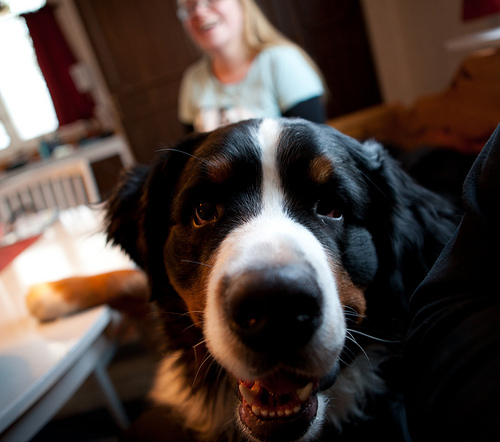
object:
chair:
[397, 47, 499, 146]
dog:
[100, 117, 458, 442]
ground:
[345, 82, 392, 113]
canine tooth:
[239, 382, 315, 418]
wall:
[377, 0, 452, 73]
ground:
[375, 86, 403, 119]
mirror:
[102, 105, 467, 433]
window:
[2, 0, 72, 142]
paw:
[21, 282, 68, 324]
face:
[167, 120, 372, 440]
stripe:
[252, 114, 292, 223]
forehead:
[175, 123, 364, 203]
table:
[0, 205, 143, 442]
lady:
[175, 0, 330, 132]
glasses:
[174, 4, 196, 20]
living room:
[4, 1, 498, 433]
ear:
[358, 140, 464, 305]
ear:
[105, 149, 170, 273]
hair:
[174, 0, 329, 105]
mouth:
[212, 353, 341, 437]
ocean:
[33, 145, 98, 209]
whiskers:
[331, 304, 396, 376]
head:
[106, 116, 452, 440]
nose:
[224, 264, 324, 353]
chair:
[4, 162, 102, 226]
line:
[253, 113, 285, 211]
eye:
[316, 196, 345, 219]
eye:
[192, 197, 222, 227]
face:
[174, 0, 244, 49]